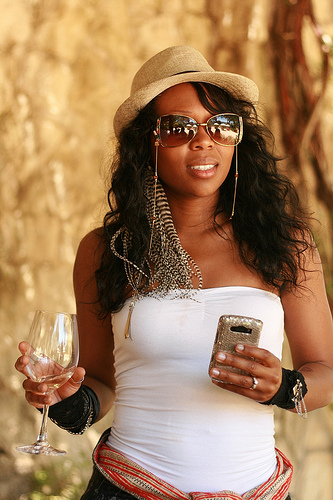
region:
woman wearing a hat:
[106, 40, 261, 118]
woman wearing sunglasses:
[143, 106, 241, 263]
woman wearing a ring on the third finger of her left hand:
[229, 336, 280, 407]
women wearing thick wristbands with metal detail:
[38, 352, 312, 436]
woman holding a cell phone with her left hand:
[207, 312, 284, 403]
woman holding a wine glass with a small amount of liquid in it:
[18, 305, 78, 460]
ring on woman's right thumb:
[13, 341, 87, 410]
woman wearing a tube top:
[100, 268, 284, 488]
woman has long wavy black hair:
[83, 80, 319, 316]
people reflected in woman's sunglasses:
[160, 115, 227, 144]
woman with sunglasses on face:
[71, 30, 311, 261]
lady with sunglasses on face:
[97, 37, 305, 295]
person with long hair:
[57, 50, 309, 294]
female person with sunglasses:
[77, 33, 317, 283]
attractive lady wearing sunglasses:
[72, 35, 310, 285]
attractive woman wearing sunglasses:
[68, 48, 316, 269]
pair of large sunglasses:
[152, 110, 245, 152]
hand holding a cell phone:
[198, 298, 276, 411]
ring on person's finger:
[246, 377, 262, 398]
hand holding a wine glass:
[15, 304, 95, 469]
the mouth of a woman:
[182, 155, 222, 180]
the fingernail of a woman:
[232, 342, 244, 353]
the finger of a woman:
[232, 338, 281, 369]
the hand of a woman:
[207, 350, 276, 405]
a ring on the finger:
[249, 372, 259, 391]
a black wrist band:
[257, 364, 309, 412]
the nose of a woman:
[186, 122, 216, 152]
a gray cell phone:
[205, 313, 265, 383]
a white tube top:
[105, 279, 287, 498]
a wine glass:
[13, 307, 84, 457]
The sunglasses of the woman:
[151, 109, 245, 156]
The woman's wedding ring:
[247, 376, 258, 390]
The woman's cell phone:
[205, 312, 264, 397]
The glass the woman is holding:
[13, 304, 83, 457]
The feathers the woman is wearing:
[109, 157, 204, 306]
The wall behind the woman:
[0, 0, 332, 499]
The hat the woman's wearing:
[106, 39, 260, 138]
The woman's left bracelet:
[263, 359, 310, 423]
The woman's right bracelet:
[35, 383, 99, 437]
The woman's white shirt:
[99, 284, 285, 499]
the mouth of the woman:
[181, 153, 222, 178]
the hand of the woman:
[205, 339, 281, 403]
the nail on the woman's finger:
[232, 341, 247, 355]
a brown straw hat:
[110, 39, 262, 142]